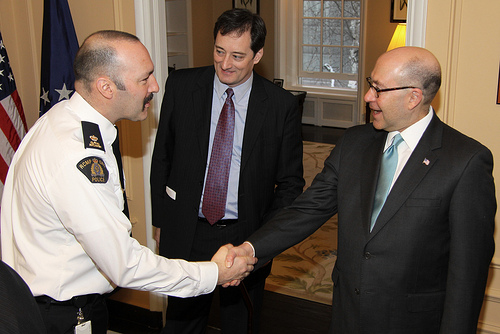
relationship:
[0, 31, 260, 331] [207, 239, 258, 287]
male shaking hands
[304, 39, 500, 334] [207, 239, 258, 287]
man shaking hands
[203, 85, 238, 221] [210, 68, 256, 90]
tie around neck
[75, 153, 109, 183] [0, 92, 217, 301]
patch on a shirt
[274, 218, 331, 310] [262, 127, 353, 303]
rug on floor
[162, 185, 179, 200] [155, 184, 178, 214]
pamphlet in pocket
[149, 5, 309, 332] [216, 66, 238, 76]
man has smile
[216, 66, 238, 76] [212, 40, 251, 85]
smile on face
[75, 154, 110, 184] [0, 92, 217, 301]
badge on shirt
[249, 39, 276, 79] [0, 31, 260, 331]
ear on male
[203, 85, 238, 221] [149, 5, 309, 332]
tie on man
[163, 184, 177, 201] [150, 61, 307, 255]
white paper in jacket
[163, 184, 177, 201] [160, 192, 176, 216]
white paper in pocket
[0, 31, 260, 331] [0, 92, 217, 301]
male in shirt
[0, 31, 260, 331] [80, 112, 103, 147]
male wearing isignia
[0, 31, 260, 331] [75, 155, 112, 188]
male wearing isignia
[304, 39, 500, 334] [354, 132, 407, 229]
man wearing tie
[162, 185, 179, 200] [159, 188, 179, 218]
pamphlet in pocket